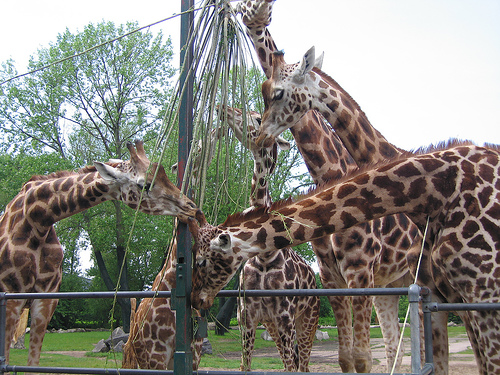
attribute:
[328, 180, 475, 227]
spots —  brown and white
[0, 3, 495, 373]
giraffes —  in group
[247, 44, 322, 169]
head — bent down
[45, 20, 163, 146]
tree —  some,  large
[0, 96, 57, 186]
tree —  large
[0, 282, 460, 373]
fence —  metallic 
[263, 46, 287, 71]
horn — black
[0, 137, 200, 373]
giraffe —   six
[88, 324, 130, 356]
rocks — gray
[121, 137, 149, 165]
horns —  short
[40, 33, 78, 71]
leaves — green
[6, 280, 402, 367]
bars — metal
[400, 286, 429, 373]
pole — metal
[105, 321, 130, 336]
top — pointy